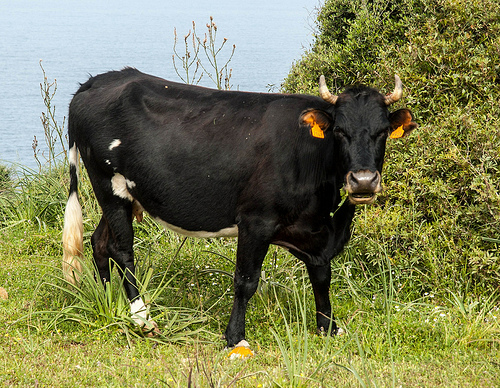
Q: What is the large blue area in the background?
A: Water.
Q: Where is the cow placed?
A: On grass.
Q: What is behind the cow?
A: Bushes.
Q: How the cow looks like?
A: Hungry.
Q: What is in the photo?
A: Cow.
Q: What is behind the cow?
A: Water.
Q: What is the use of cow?
A: Milk.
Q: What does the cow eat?
A: Grass.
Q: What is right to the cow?
A: Bushes.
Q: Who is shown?
A: A bull.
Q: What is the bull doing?
A: Eating.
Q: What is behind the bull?
A: Water.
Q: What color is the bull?
A: Black and white.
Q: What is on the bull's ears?
A: Tags.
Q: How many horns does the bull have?
A: Two.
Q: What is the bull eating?
A: Grass.